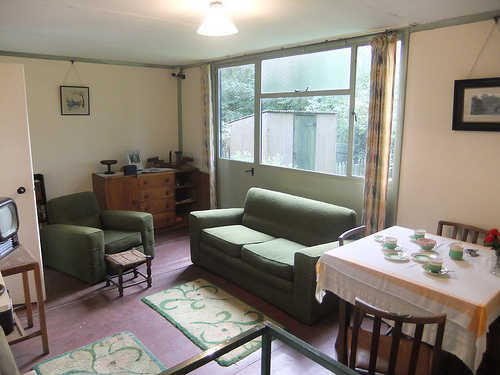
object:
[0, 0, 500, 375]
room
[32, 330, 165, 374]
rug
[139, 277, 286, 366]
rug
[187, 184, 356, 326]
sofa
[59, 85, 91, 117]
picture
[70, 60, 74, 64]
hook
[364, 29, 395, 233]
drape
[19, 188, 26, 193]
knob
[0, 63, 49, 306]
door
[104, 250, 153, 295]
stool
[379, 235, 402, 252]
cups and saucers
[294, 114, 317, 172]
door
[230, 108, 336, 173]
shed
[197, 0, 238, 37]
light fixture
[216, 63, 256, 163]
window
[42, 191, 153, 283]
chair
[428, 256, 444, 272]
tea cup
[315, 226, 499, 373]
table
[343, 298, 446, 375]
chair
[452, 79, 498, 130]
picture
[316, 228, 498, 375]
table cloth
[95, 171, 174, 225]
dresser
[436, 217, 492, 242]
chair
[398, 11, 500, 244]
wall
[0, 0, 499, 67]
ceiling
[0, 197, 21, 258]
part of tv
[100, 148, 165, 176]
knicknacks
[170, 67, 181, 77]
security camera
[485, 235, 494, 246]
rose